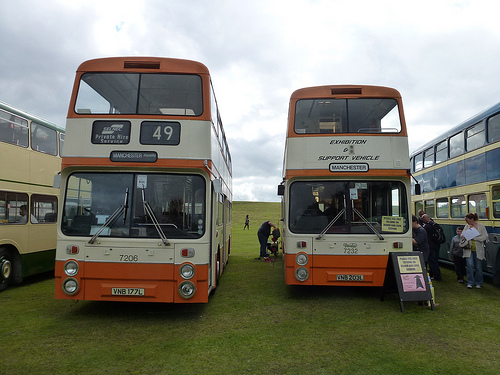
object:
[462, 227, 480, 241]
paper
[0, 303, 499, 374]
grass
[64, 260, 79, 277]
lights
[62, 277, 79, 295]
lights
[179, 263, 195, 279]
lights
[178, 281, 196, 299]
lights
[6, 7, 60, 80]
clouds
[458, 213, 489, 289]
person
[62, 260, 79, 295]
headlights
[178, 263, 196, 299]
headlights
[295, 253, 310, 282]
headlights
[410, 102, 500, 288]
bus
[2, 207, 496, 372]
grass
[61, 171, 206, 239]
window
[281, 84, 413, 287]
with orange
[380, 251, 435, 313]
billboard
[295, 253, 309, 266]
headlight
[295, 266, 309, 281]
headlight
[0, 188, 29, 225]
windows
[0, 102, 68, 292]
bus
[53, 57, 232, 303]
bus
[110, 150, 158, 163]
sign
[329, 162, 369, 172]
sign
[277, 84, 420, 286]
bus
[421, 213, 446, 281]
people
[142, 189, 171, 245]
windshield wiper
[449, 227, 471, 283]
people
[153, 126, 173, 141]
number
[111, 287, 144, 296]
license plate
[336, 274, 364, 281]
license plate